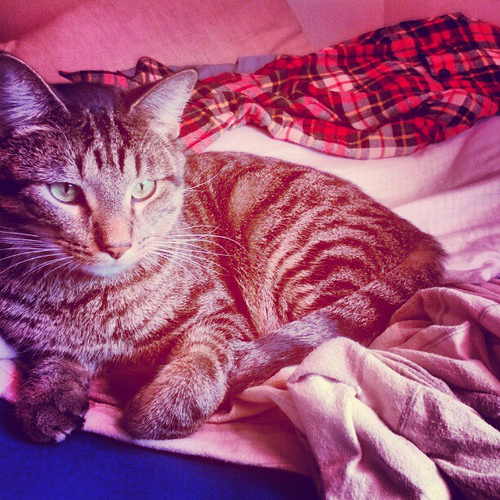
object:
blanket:
[57, 12, 500, 159]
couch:
[0, 0, 499, 500]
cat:
[0, 50, 451, 445]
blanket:
[0, 276, 499, 499]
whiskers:
[137, 224, 249, 295]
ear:
[124, 66, 197, 141]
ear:
[0, 51, 71, 131]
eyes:
[128, 178, 158, 208]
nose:
[103, 244, 130, 260]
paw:
[13, 379, 91, 445]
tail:
[229, 246, 446, 401]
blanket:
[0, 360, 314, 476]